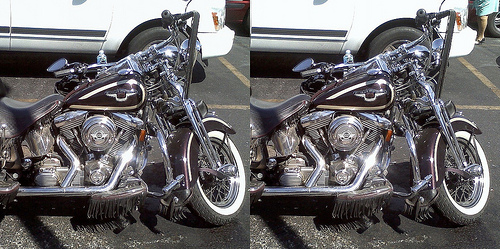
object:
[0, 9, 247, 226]
bike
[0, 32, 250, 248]
pavement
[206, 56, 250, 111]
lines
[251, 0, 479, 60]
vehicle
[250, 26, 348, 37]
stripe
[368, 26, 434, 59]
tire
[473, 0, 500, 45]
woman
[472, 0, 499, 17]
skirt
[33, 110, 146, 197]
engine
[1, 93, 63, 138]
seat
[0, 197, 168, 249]
shadow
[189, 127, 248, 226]
tire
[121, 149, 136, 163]
sunshine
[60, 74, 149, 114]
gas tank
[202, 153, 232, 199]
forks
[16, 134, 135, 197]
exhaust pipe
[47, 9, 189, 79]
handle bars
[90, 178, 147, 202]
footboard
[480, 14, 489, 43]
leg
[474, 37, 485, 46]
shoes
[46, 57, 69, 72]
mirror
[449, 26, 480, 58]
bumper